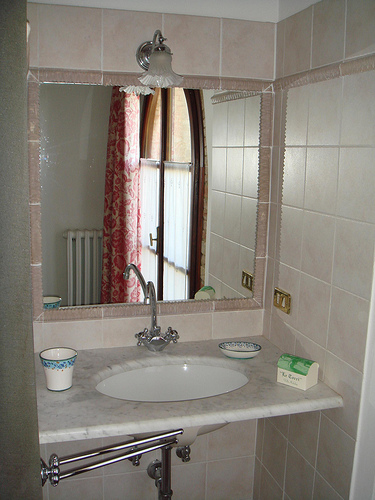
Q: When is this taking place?
A: Daytime.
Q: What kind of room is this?
A: Bathroom.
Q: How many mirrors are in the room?
A: One.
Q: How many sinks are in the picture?
A: One.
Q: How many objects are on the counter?
A: Three.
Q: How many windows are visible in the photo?
A: One.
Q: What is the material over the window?
A: Curtains.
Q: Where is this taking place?
A: In an older home's bathroom.